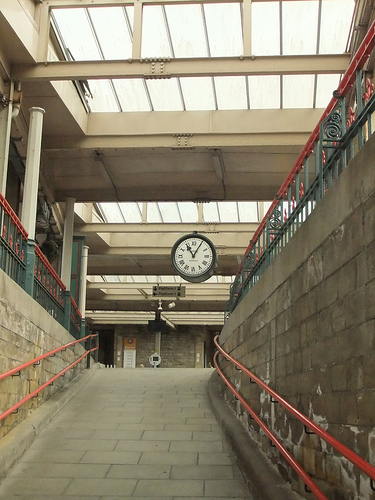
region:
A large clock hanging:
[126, 209, 273, 316]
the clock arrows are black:
[129, 207, 230, 282]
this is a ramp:
[11, 230, 308, 464]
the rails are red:
[200, 323, 296, 423]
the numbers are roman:
[163, 211, 226, 283]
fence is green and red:
[12, 269, 68, 307]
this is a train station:
[136, 281, 261, 340]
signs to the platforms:
[140, 282, 214, 322]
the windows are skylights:
[114, 192, 244, 282]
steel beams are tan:
[94, 17, 196, 97]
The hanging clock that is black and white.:
[172, 226, 217, 284]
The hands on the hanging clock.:
[185, 240, 202, 259]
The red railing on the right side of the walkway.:
[211, 330, 358, 499]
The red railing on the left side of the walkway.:
[4, 330, 96, 430]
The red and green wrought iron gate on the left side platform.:
[5, 208, 106, 331]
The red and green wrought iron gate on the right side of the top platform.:
[220, 204, 309, 303]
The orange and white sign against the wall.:
[121, 336, 139, 363]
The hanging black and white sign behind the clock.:
[147, 286, 189, 296]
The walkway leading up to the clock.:
[3, 361, 254, 499]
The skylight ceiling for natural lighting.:
[40, 3, 338, 314]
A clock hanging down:
[159, 223, 219, 281]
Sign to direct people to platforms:
[145, 279, 199, 299]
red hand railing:
[208, 338, 373, 496]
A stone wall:
[210, 243, 372, 481]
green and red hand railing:
[210, 61, 363, 316]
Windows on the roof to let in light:
[44, 4, 374, 111]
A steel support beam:
[41, 0, 342, 81]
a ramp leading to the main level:
[23, 370, 257, 498]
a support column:
[12, 106, 56, 297]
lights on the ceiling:
[86, 146, 241, 195]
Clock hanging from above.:
[167, 231, 220, 283]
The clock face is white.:
[167, 230, 217, 288]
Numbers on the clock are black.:
[171, 236, 218, 285]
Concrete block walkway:
[19, 364, 262, 495]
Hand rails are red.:
[205, 333, 366, 492]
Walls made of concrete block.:
[206, 296, 369, 493]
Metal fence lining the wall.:
[220, 95, 369, 309]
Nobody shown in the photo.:
[2, 4, 371, 490]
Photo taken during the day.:
[30, 1, 354, 298]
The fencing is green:
[0, 223, 102, 362]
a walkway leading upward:
[5, 310, 271, 496]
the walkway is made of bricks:
[23, 356, 255, 497]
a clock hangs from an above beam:
[85, 217, 253, 280]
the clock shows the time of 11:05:
[169, 228, 223, 284]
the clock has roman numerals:
[170, 230, 220, 283]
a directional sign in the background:
[150, 281, 188, 299]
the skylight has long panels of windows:
[48, 4, 361, 237]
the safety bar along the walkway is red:
[205, 325, 372, 495]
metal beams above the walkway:
[17, 12, 364, 267]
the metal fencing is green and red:
[230, 61, 369, 288]